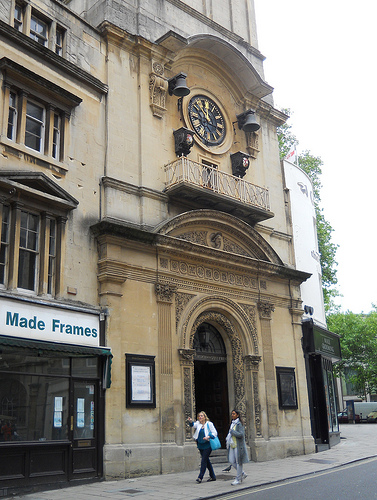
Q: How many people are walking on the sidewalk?
A: Two.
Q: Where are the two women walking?
A: On the sidewalk.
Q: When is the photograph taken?
A: Daytime.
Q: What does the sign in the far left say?
A: "Made Frames".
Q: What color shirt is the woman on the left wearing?
A: White.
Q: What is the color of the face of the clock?
A: Black.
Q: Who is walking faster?
A: The woman in the white shirt.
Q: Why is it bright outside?
A: It is daytime.